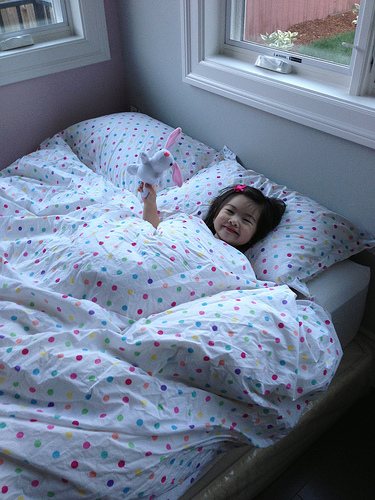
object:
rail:
[0, 3, 53, 29]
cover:
[4, 241, 190, 412]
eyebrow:
[227, 204, 238, 211]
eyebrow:
[245, 213, 256, 223]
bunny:
[127, 126, 183, 199]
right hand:
[136, 181, 158, 204]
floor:
[298, 450, 338, 491]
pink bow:
[234, 184, 247, 193]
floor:
[349, 408, 371, 495]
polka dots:
[212, 325, 218, 332]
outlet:
[130, 104, 141, 112]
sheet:
[305, 259, 370, 312]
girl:
[138, 181, 286, 252]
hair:
[204, 184, 286, 253]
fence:
[244, 0, 354, 41]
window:
[182, 1, 375, 154]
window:
[4, 2, 72, 47]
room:
[0, 0, 375, 500]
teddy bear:
[197, 188, 291, 246]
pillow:
[58, 111, 220, 198]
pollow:
[152, 142, 375, 284]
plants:
[259, 29, 297, 50]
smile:
[212, 190, 260, 245]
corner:
[348, 256, 373, 343]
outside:
[244, 0, 362, 64]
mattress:
[183, 332, 375, 499]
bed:
[0, 109, 375, 422]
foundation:
[227, 375, 373, 497]